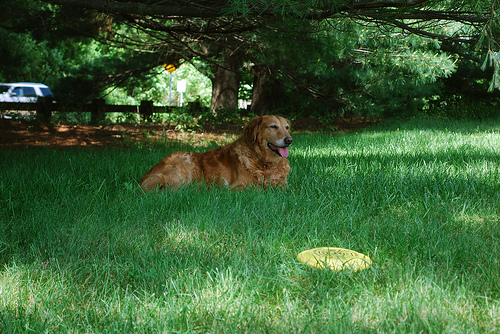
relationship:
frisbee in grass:
[294, 240, 380, 273] [7, 141, 500, 330]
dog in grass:
[128, 112, 298, 195] [7, 141, 500, 330]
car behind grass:
[0, 80, 60, 121] [7, 141, 500, 330]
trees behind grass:
[28, 1, 500, 127] [7, 141, 500, 330]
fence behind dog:
[1, 92, 319, 124] [128, 112, 298, 195]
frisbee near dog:
[294, 240, 380, 273] [128, 112, 298, 195]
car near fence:
[0, 80, 60, 121] [1, 92, 319, 124]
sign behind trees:
[161, 49, 187, 109] [28, 1, 500, 127]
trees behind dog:
[28, 1, 500, 127] [128, 112, 298, 195]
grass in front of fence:
[7, 141, 500, 330] [1, 92, 319, 124]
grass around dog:
[7, 141, 500, 330] [128, 112, 298, 195]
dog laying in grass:
[128, 112, 298, 195] [7, 141, 500, 330]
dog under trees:
[128, 112, 298, 195] [28, 1, 500, 127]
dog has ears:
[128, 112, 298, 195] [244, 116, 264, 144]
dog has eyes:
[128, 112, 298, 195] [266, 121, 291, 131]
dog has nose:
[128, 112, 298, 195] [282, 132, 294, 146]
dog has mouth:
[128, 112, 298, 195] [266, 138, 292, 160]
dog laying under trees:
[128, 112, 298, 195] [28, 1, 500, 127]